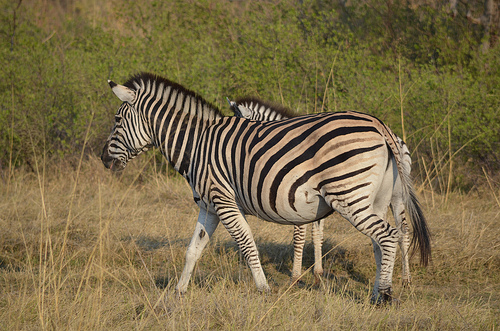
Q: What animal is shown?
A: Zebra.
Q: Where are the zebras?
A: In the wild.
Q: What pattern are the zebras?
A: Stripes.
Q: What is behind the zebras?
A: Plants.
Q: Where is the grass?
A: On the ground.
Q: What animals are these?
A: Zebras.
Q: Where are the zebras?
A: In the field.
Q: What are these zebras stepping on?
A: Tall brown grass.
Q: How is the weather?
A: Sunny.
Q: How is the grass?
A: Dry and brown.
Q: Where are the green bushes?
A: Next to brown grass.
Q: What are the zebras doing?
A: Playing in the field.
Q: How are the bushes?
A: Green.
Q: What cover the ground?
A: Brown grass.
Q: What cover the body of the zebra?
A: Black and white stripes.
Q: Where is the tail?
A: On the butt.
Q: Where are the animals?
A: In a field.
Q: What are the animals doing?
A: Walking through a field.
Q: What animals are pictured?
A: Zebra.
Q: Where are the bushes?
A: On the outside of the field.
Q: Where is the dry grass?
A: By the zebra.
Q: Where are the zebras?
A: In the wild.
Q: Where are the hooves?
A: On the legs of the zebra.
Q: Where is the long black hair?
A: On the zebra tail.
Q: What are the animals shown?
A: Zebras.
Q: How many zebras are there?
A: Two.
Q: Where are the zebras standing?
A: Grass.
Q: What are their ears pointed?
A: Forward.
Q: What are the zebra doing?
A: Walking.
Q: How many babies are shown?
A: One.